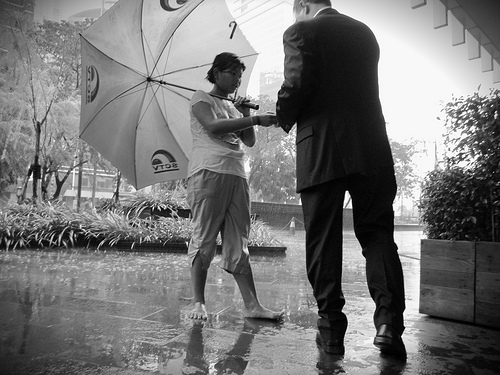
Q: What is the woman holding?
A: An umbrella.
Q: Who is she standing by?
A: A man.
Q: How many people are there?
A: Two.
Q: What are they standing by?
A: Plants.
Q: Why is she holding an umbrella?
A: It was raining.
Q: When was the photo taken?
A: During the day.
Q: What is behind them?
A: Trees.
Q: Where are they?
A: On the sidewalk.